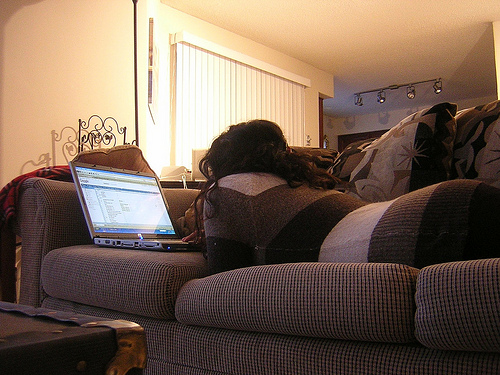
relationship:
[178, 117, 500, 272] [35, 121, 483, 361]
woman on couch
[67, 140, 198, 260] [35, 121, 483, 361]
laptop on couch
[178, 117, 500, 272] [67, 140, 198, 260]
woman using laptop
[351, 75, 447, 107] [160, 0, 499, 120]
lighting on ceiling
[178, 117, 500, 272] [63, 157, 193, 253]
woman with laptop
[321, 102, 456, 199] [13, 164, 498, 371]
pillow on couch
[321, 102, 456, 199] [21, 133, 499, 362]
pillow on couch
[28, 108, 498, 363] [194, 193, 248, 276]
couch has arm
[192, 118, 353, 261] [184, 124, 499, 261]
hair of woman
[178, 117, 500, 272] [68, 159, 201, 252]
woman using a laptop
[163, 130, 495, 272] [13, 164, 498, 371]
woman on a couch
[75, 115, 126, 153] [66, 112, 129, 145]
top of shelving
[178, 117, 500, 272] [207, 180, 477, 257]
woman wearing a sweater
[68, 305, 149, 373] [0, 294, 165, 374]
corner of table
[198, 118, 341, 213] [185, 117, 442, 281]
hair of woman